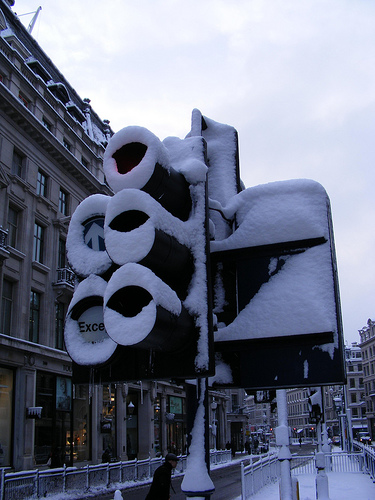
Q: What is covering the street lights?
A: Snow.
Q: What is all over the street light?
A: Snow.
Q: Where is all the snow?
A: On top of the street light.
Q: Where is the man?
A: Below the street light.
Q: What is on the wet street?
A: Melted snow.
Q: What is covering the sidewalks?
A: Snow.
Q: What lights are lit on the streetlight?
A: Yellow.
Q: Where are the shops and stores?
A: Along the bottom of the buildings.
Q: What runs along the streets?
A: Fences.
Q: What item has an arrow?
A: The traffic light.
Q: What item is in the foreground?
A: Traffic light.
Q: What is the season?
A: Winter.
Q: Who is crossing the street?
A: An old man.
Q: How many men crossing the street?
A: Two.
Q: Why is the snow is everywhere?
A: It is winter.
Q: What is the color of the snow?
A: White.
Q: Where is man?
A: On the street.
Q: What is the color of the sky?
A: White and gray.